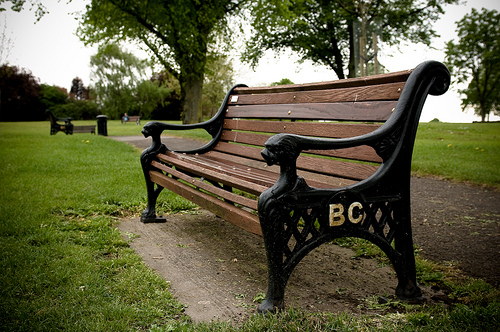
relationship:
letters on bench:
[315, 193, 351, 223] [164, 87, 408, 242]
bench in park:
[164, 87, 408, 242] [25, 38, 426, 243]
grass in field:
[25, 190, 125, 284] [6, 149, 93, 297]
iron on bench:
[144, 123, 199, 141] [164, 87, 408, 242]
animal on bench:
[252, 139, 296, 171] [164, 87, 408, 242]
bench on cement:
[164, 87, 408, 242] [168, 231, 278, 290]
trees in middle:
[88, 14, 442, 76] [173, 21, 315, 95]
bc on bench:
[297, 194, 375, 230] [164, 87, 408, 242]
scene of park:
[25, 19, 450, 271] [25, 38, 426, 243]